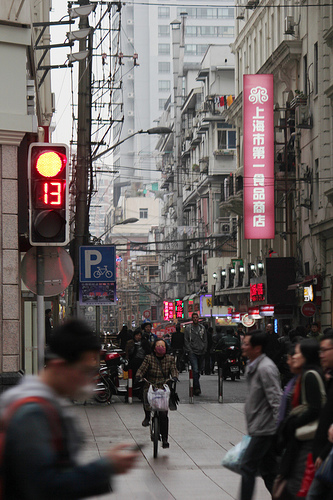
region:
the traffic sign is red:
[21, 142, 71, 245]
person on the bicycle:
[128, 336, 192, 454]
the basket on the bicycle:
[135, 383, 173, 412]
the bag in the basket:
[147, 386, 169, 404]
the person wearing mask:
[150, 337, 172, 360]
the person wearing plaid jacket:
[135, 350, 184, 387]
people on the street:
[225, 324, 329, 471]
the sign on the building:
[233, 72, 304, 251]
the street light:
[100, 114, 174, 160]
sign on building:
[242, 271, 277, 316]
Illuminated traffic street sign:
[26, 141, 74, 248]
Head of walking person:
[39, 317, 106, 399]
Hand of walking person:
[104, 436, 145, 480]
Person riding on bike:
[136, 338, 181, 463]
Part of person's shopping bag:
[217, 433, 256, 472]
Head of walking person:
[237, 331, 271, 358]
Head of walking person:
[289, 336, 325, 370]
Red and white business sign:
[239, 70, 279, 240]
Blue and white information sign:
[74, 239, 122, 307]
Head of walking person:
[317, 333, 330, 372]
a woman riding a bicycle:
[136, 336, 179, 458]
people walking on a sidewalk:
[221, 329, 330, 498]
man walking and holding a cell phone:
[3, 317, 142, 499]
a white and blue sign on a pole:
[78, 243, 116, 282]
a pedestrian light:
[27, 139, 69, 246]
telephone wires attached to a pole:
[67, 3, 123, 227]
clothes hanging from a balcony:
[214, 94, 235, 111]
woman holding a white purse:
[293, 369, 325, 440]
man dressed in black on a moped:
[214, 327, 237, 383]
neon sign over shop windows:
[161, 298, 184, 319]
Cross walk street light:
[26, 143, 68, 245]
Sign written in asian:
[243, 73, 274, 239]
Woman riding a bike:
[133, 336, 179, 459]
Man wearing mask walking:
[0, 316, 146, 499]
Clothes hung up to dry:
[211, 93, 233, 110]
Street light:
[90, 126, 174, 161]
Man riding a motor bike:
[211, 326, 241, 381]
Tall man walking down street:
[182, 311, 209, 397]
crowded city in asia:
[0, 0, 332, 499]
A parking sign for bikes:
[78, 245, 115, 370]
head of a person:
[36, 320, 105, 392]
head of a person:
[150, 334, 171, 356]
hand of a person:
[85, 427, 164, 482]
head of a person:
[230, 321, 274, 361]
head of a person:
[284, 330, 319, 366]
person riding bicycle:
[121, 328, 191, 459]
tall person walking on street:
[177, 310, 219, 403]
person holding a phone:
[99, 433, 154, 481]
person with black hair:
[229, 317, 274, 364]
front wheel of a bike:
[140, 415, 171, 463]